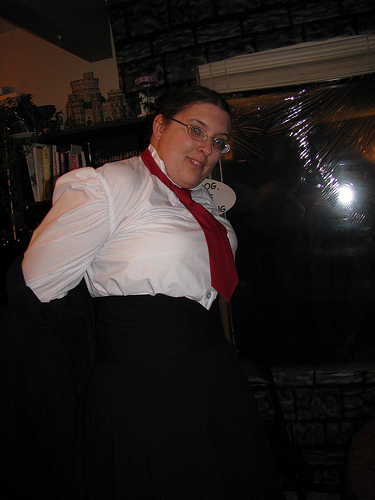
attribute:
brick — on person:
[290, 383, 346, 423]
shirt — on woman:
[20, 144, 238, 311]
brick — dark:
[190, 18, 240, 45]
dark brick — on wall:
[111, 6, 317, 66]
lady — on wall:
[21, 74, 274, 499]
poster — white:
[199, 178, 236, 215]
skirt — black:
[52, 292, 281, 496]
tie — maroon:
[156, 157, 276, 348]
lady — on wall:
[1, 78, 244, 497]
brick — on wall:
[174, 20, 209, 38]